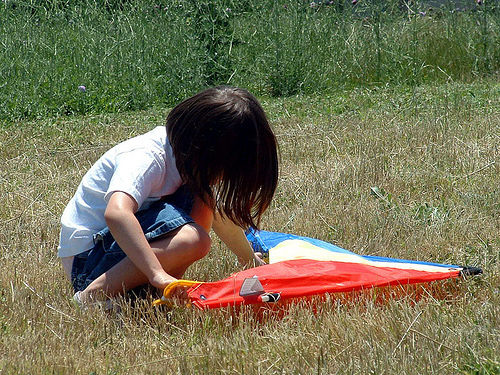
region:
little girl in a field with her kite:
[11, 8, 486, 354]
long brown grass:
[350, 310, 467, 370]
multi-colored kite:
[276, 220, 481, 305]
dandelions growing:
[365, 175, 435, 215]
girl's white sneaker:
[65, 287, 125, 317]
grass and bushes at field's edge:
[322, 25, 423, 82]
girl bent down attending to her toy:
[50, 50, 490, 345]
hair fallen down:
[195, 160, 280, 232]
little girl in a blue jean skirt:
[61, 56, 216, 322]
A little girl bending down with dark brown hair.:
[58, 87, 280, 310]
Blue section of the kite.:
[242, 222, 463, 267]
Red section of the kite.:
[189, 260, 458, 307]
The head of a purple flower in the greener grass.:
[76, 82, 86, 92]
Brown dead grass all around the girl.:
[6, 114, 498, 373]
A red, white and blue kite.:
[156, 223, 484, 311]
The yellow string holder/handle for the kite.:
[148, 279, 205, 309]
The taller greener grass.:
[1, 2, 498, 116]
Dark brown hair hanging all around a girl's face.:
[163, 89, 281, 234]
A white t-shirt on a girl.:
[56, 124, 182, 257]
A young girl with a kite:
[51, 84, 486, 324]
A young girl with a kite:
[51, 83, 488, 320]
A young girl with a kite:
[51, 82, 487, 312]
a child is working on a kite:
[4, 2, 495, 369]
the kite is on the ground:
[173, 218, 485, 317]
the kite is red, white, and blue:
[173, 215, 477, 318]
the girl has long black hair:
[164, 80, 283, 235]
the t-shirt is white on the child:
[53, 122, 187, 256]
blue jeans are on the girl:
[63, 205, 200, 287]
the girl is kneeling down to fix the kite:
[66, 82, 297, 335]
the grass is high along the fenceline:
[6, 5, 496, 112]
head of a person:
[171, 79, 273, 196]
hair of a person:
[188, 100, 253, 173]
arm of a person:
[222, 202, 262, 275]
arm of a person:
[100, 222, 165, 297]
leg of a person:
[93, 252, 165, 297]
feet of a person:
[69, 295, 131, 329]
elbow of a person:
[88, 208, 138, 235]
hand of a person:
[231, 225, 284, 293]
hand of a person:
[157, 253, 184, 310]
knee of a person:
[202, 225, 227, 258]